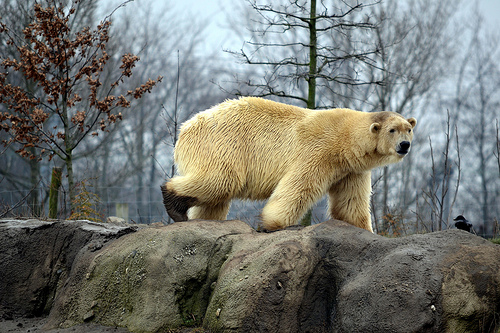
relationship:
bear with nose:
[159, 96, 417, 235] [397, 134, 407, 158]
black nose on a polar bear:
[394, 137, 412, 157] [155, 85, 415, 235]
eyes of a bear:
[401, 122, 410, 133] [159, 96, 417, 235]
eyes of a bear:
[390, 129, 412, 133] [159, 96, 417, 235]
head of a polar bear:
[362, 98, 419, 167] [155, 85, 415, 235]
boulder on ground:
[0, 219, 495, 332] [4, 311, 82, 331]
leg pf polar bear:
[173, 140, 246, 209] [150, 90, 433, 247]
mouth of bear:
[395, 149, 409, 157] [159, 96, 417, 235]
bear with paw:
[159, 96, 417, 235] [157, 180, 198, 221]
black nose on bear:
[400, 141, 411, 150] [168, 87, 397, 231]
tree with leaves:
[14, 8, 87, 218] [12, 8, 127, 177]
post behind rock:
[46, 164, 66, 220] [12, 211, 225, 308]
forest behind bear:
[31, 8, 483, 212] [167, 105, 412, 225]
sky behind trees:
[1, 1, 498, 230] [2, 1, 497, 235]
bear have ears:
[159, 96, 417, 235] [368, 117, 381, 134]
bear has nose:
[159, 96, 417, 235] [399, 142, 416, 151]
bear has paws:
[159, 96, 417, 235] [143, 164, 223, 209]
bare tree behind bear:
[298, 13, 363, 94] [159, 96, 417, 235]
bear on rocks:
[159, 96, 417, 235] [5, 212, 486, 312]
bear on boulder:
[138, 73, 438, 244] [60, 213, 454, 314]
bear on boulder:
[159, 96, 417, 235] [60, 213, 454, 314]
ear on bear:
[368, 123, 380, 133] [159, 96, 417, 235]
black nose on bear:
[400, 141, 411, 150] [163, 95, 427, 226]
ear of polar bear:
[408, 117, 418, 128] [155, 85, 415, 235]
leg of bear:
[161, 163, 248, 222] [159, 96, 417, 235]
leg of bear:
[256, 161, 327, 233] [159, 96, 417, 235]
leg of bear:
[331, 172, 374, 231] [159, 96, 417, 235]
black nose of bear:
[400, 141, 411, 150] [159, 96, 417, 235]